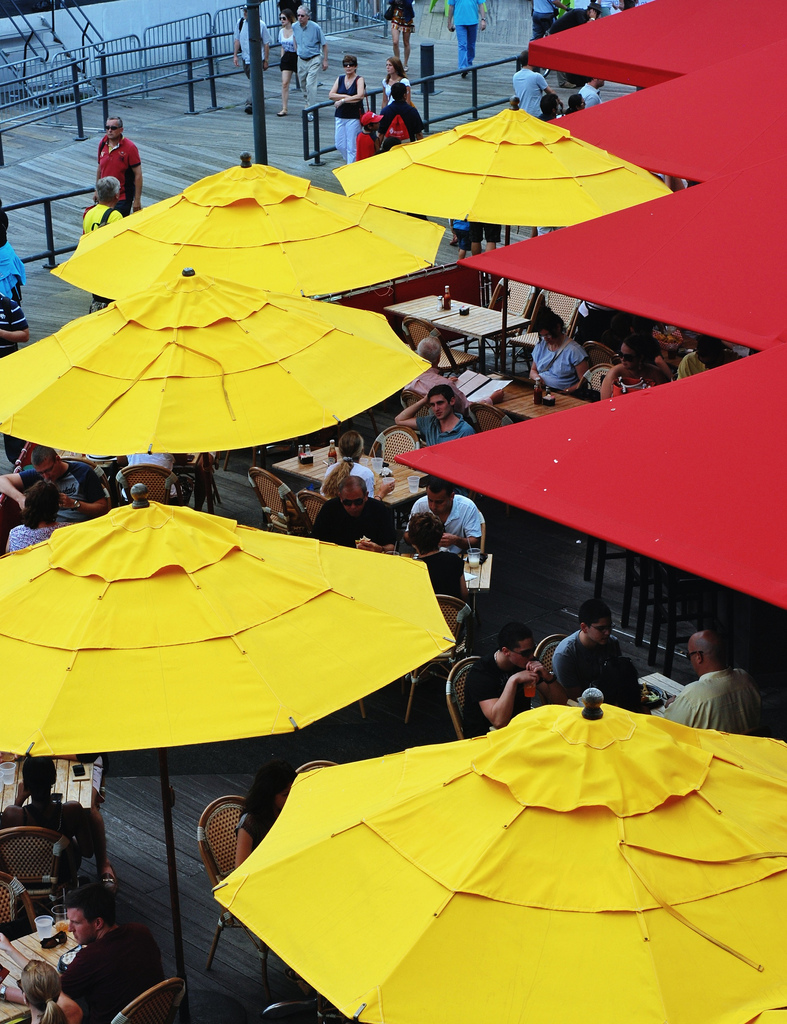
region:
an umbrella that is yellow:
[357, 123, 579, 262]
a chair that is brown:
[517, 628, 584, 695]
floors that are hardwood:
[116, 799, 158, 864]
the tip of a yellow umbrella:
[123, 482, 163, 515]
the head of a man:
[42, 880, 109, 947]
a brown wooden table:
[15, 921, 80, 974]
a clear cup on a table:
[22, 916, 62, 945]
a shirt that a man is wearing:
[548, 637, 608, 688]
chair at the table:
[113, 976, 195, 1014]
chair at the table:
[259, 999, 280, 1007]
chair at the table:
[5, 838, 53, 891]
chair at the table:
[251, 472, 304, 510]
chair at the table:
[377, 433, 408, 463]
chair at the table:
[494, 279, 502, 305]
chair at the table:
[1, 817, 31, 861]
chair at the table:
[296, 758, 338, 772]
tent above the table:
[442, 859, 685, 999]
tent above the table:
[11, 564, 95, 703]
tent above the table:
[621, 473, 739, 584]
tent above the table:
[392, 135, 522, 226]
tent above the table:
[538, 13, 649, 102]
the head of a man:
[406, 377, 471, 426]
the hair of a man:
[411, 377, 455, 428]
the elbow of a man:
[375, 390, 428, 441]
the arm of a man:
[472, 660, 541, 740]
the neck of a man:
[478, 633, 525, 691]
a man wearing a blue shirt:
[404, 361, 475, 450]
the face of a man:
[321, 467, 388, 538]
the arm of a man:
[368, 359, 466, 437]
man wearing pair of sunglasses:
[336, 491, 373, 513]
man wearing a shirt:
[316, 493, 398, 550]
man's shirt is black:
[308, 488, 396, 553]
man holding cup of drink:
[517, 665, 542, 699]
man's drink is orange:
[513, 668, 543, 706]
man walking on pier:
[83, 106, 143, 225]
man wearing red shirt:
[90, 134, 142, 211]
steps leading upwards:
[4, 19, 98, 114]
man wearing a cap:
[354, 105, 382, 128]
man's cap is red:
[357, 105, 382, 129]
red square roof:
[401, 2, 785, 631]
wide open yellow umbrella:
[215, 680, 781, 1021]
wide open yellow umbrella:
[1, 497, 470, 788]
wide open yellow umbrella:
[1, 270, 397, 452]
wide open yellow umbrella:
[65, 162, 441, 308]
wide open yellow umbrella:
[341, 101, 674, 257]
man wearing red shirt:
[86, 109, 147, 221]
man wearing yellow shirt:
[65, 180, 136, 259]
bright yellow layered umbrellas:
[10, 80, 783, 1023]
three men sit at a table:
[445, 606, 753, 737]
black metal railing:
[285, 48, 531, 170]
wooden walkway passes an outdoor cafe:
[0, 17, 598, 327]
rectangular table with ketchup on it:
[387, 285, 534, 342]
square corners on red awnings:
[386, 0, 785, 617]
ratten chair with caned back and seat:
[197, 787, 272, 983]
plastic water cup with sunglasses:
[34, 903, 72, 959]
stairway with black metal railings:
[11, 5, 100, 106]